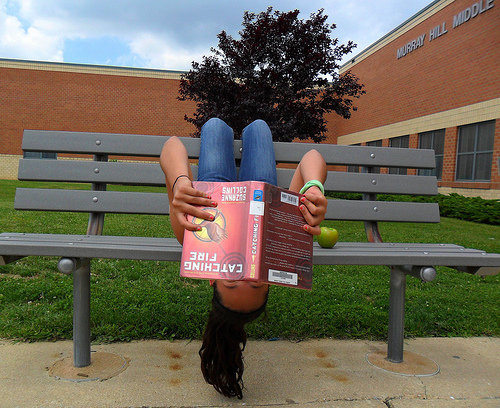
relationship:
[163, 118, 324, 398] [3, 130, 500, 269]
girl laying bench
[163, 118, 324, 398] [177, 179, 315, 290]
girl reading book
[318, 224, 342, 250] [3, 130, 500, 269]
apple on bench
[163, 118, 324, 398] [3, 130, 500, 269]
girl on bench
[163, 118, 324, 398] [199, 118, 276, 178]
girl wearing jeans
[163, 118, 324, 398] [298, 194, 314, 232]
girl wearing nail polish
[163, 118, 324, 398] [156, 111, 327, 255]
girl outside sitting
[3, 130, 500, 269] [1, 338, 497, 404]
bench on sidewalk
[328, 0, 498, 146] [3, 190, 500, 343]
school on grass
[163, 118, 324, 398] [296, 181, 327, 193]
girl wearing bracelet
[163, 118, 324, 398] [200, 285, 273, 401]
girl dark hair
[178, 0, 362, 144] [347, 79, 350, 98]
tree with leaves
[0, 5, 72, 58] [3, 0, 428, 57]
clouds in sky